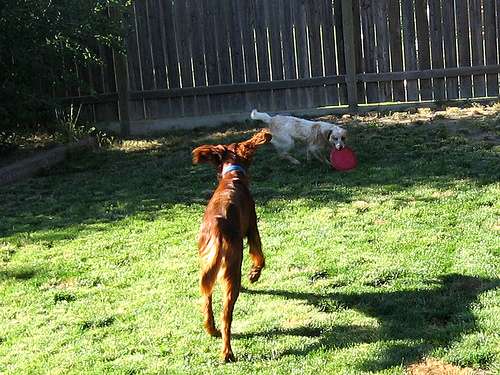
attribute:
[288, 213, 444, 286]
grass — green, light, dark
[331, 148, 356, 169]
frisbee — red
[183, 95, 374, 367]
two dogs — playing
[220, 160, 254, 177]
collar — blue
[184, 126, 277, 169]
ears — flying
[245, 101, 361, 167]
dog — white, brown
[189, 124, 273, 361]
dog — red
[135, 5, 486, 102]
fence — wooden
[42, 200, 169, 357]
lawn — green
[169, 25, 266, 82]
boards — wooden